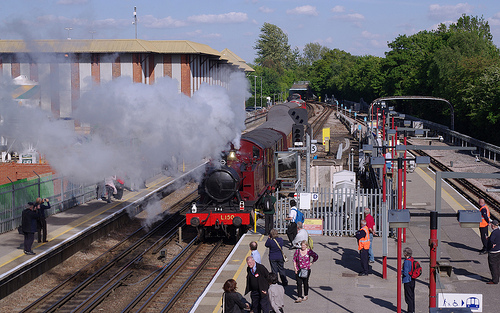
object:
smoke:
[4, 69, 255, 232]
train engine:
[181, 129, 287, 235]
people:
[284, 198, 305, 245]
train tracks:
[31, 188, 227, 312]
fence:
[275, 186, 388, 235]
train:
[197, 83, 312, 244]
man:
[354, 221, 370, 275]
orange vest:
[353, 225, 371, 250]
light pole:
[426, 210, 439, 312]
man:
[401, 246, 417, 312]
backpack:
[407, 258, 423, 279]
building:
[0, 36, 258, 136]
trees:
[293, 51, 383, 112]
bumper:
[233, 218, 244, 226]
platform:
[187, 112, 500, 313]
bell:
[225, 151, 239, 163]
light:
[383, 208, 410, 236]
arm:
[413, 206, 457, 220]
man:
[245, 256, 273, 312]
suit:
[246, 265, 272, 313]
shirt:
[399, 256, 412, 288]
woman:
[264, 229, 291, 286]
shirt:
[265, 237, 288, 261]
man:
[21, 199, 42, 255]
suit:
[21, 209, 38, 254]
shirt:
[248, 266, 259, 274]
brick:
[180, 58, 193, 94]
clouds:
[0, 1, 500, 73]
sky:
[0, 2, 500, 68]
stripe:
[183, 232, 246, 312]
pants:
[404, 280, 417, 312]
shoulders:
[403, 259, 420, 263]